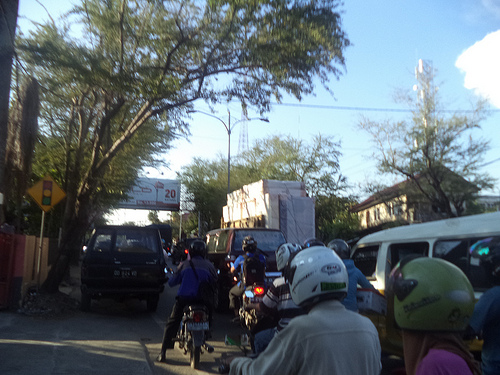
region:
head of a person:
[283, 242, 348, 307]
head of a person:
[378, 261, 474, 338]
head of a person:
[325, 236, 359, 261]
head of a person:
[237, 234, 266, 256]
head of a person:
[265, 230, 310, 284]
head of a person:
[182, 240, 216, 267]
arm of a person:
[153, 256, 190, 293]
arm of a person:
[226, 337, 278, 372]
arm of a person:
[223, 248, 251, 282]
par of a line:
[321, 267, 344, 301]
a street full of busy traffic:
[12, 10, 497, 330]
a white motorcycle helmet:
[280, 251, 365, 307]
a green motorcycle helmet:
[382, 259, 467, 336]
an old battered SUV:
[75, 221, 170, 304]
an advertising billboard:
[135, 165, 219, 232]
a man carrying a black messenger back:
[171, 250, 248, 319]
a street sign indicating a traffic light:
[22, 161, 78, 238]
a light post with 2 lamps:
[185, 103, 279, 183]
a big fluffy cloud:
[442, 22, 497, 87]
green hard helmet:
[373, 248, 481, 342]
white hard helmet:
[276, 244, 358, 311]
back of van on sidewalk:
[73, 220, 169, 322]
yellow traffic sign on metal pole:
[18, 169, 70, 294]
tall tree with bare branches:
[350, 49, 498, 222]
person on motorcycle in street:
[153, 229, 223, 372]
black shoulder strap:
[183, 255, 210, 290]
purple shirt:
[402, 337, 468, 374]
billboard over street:
[114, 171, 184, 214]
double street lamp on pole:
[181, 104, 273, 186]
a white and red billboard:
[107, 150, 207, 217]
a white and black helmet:
[274, 238, 353, 313]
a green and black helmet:
[381, 245, 466, 332]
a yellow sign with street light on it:
[19, 161, 64, 220]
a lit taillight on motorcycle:
[249, 280, 272, 305]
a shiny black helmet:
[160, 227, 212, 264]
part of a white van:
[327, 195, 497, 317]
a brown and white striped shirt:
[252, 270, 314, 352]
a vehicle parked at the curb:
[64, 209, 196, 339]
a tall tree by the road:
[0, 0, 327, 304]